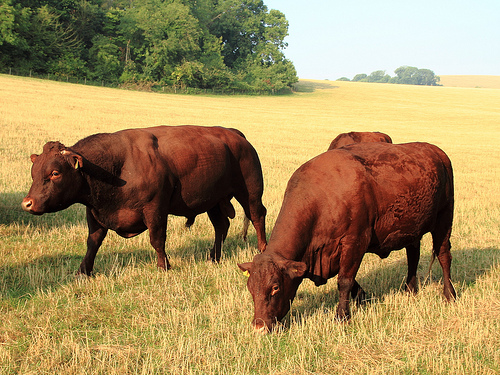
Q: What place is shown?
A: It is a field.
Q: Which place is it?
A: It is a field.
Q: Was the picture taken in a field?
A: Yes, it was taken in a field.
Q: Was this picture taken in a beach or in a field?
A: It was taken at a field.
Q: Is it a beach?
A: No, it is a field.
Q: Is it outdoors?
A: Yes, it is outdoors.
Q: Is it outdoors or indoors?
A: It is outdoors.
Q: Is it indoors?
A: No, it is outdoors.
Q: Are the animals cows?
A: Yes, all the animals are cows.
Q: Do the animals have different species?
A: No, all the animals are cows.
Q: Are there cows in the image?
A: Yes, there is a cow.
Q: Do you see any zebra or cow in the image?
A: Yes, there is a cow.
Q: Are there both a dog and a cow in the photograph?
A: No, there is a cow but no dogs.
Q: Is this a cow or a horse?
A: This is a cow.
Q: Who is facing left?
A: The cow is facing left.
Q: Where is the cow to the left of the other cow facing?
A: The cow is facing left.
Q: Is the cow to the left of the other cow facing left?
A: Yes, the cow is facing left.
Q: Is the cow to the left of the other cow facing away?
A: No, the cow is facing left.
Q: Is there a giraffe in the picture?
A: No, there are no giraffes.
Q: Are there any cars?
A: No, there are no cars.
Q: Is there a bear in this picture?
A: No, there are no bears.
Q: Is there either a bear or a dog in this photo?
A: No, there are no bears or dogs.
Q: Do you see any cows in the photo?
A: Yes, there is a cow.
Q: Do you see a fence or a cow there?
A: Yes, there is a cow.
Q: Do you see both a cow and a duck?
A: No, there is a cow but no ducks.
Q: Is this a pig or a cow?
A: This is a cow.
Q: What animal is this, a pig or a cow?
A: This is a cow.